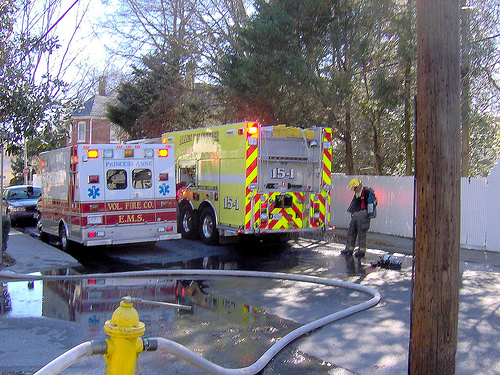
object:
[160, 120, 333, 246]
fire truck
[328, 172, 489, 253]
fence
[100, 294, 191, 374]
hydrant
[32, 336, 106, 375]
fire hose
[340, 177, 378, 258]
firefighter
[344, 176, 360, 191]
helmet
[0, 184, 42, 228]
car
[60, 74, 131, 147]
brick house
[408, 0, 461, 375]
post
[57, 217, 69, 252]
wheel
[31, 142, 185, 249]
ambulance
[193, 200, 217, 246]
wheels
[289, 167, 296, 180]
number one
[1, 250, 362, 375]
water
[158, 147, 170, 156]
light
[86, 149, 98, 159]
light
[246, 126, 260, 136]
light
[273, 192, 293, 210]
gear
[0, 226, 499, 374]
road